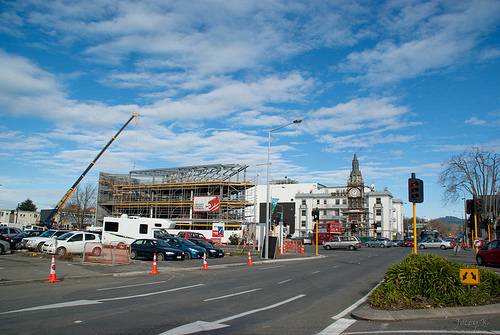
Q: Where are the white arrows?
A: On the street.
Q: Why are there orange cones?
A: Construction site.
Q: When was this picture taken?
A: Daytime.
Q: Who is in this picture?
A: No one.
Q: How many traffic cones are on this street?
A: Four.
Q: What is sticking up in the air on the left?
A: A crane.